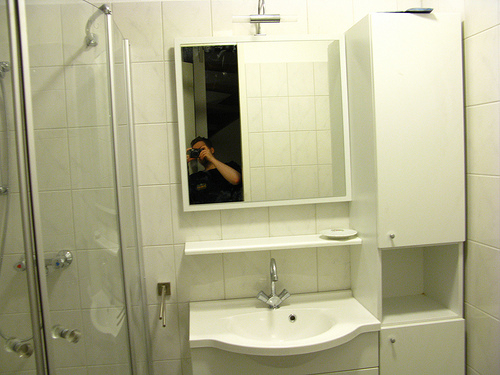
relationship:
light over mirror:
[233, 5, 288, 38] [169, 38, 251, 206]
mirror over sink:
[169, 38, 251, 206] [188, 304, 370, 347]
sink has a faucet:
[188, 304, 370, 347] [248, 256, 294, 310]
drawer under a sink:
[221, 354, 368, 373] [188, 304, 370, 347]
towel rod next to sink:
[151, 279, 174, 331] [188, 304, 370, 347]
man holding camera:
[185, 136, 240, 204] [188, 146, 201, 158]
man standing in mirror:
[185, 136, 240, 204] [169, 38, 251, 206]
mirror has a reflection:
[169, 38, 251, 206] [203, 66, 242, 118]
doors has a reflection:
[19, 12, 117, 164] [203, 66, 242, 118]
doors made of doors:
[19, 12, 117, 164] [19, 12, 117, 164]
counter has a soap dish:
[277, 235, 324, 252] [312, 224, 367, 246]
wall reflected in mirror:
[243, 60, 325, 193] [169, 38, 251, 206]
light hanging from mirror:
[233, 5, 288, 38] [169, 38, 251, 206]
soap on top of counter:
[318, 225, 358, 241] [183, 229, 361, 256]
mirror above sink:
[169, 38, 251, 206] [188, 304, 370, 347]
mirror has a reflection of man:
[169, 38, 251, 206] [185, 136, 240, 204]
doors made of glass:
[19, 12, 117, 164] [66, 50, 109, 102]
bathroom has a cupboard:
[19, 6, 492, 373] [360, 14, 472, 246]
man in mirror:
[189, 132, 231, 195] [169, 38, 251, 206]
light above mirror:
[233, 5, 288, 38] [169, 38, 251, 206]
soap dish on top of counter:
[312, 224, 367, 246] [183, 229, 361, 256]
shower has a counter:
[6, 4, 139, 367] [183, 229, 361, 256]